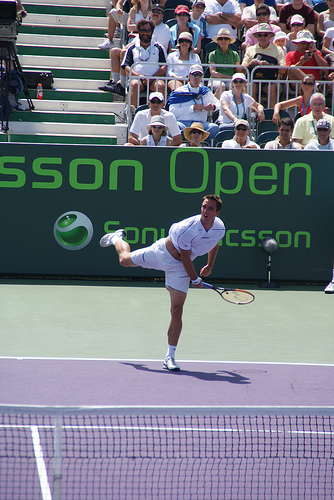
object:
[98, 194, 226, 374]
player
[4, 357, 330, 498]
court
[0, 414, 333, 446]
lines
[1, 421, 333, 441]
tape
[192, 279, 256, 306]
tennis racket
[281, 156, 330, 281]
wall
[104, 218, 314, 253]
advertisements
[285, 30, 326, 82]
man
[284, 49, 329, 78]
shirt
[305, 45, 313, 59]
phone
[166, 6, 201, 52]
woman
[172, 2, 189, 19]
hat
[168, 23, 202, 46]
sweater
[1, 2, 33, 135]
television camera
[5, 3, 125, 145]
steps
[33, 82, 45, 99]
bottle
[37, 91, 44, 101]
sports drink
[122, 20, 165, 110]
man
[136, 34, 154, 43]
beard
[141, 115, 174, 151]
people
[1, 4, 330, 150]
stands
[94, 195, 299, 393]
tennis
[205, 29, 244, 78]
person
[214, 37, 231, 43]
glasses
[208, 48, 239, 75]
shirt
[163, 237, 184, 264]
belly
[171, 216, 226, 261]
shirt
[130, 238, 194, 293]
pants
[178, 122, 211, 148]
woman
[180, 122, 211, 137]
hat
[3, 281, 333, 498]
tennis court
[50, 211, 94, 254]
logo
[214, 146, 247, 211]
letter p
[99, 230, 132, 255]
tennis shoes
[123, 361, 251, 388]
shadow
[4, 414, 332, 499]
mesh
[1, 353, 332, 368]
foul line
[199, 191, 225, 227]
head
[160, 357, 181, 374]
foot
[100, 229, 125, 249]
foot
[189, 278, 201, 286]
sweatband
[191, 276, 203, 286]
wrist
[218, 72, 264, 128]
woman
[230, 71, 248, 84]
hat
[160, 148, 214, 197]
tournament sign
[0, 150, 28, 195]
green letters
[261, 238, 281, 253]
tennis ball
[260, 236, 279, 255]
flight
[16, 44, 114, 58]
riser